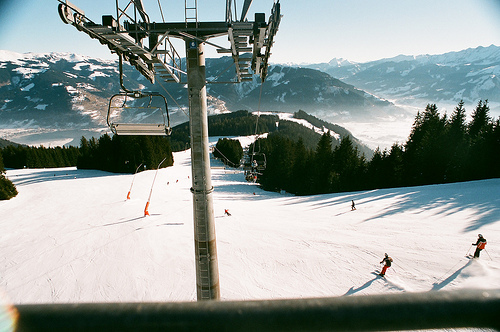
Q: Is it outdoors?
A: Yes, it is outdoors.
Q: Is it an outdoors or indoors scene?
A: It is outdoors.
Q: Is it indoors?
A: No, it is outdoors.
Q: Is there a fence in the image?
A: No, there are no fences.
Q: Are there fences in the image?
A: No, there are no fences.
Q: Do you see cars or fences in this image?
A: No, there are no fences or cars.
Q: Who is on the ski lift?
A: The people are on the ski lift.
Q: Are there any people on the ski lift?
A: Yes, there are people on the ski lift.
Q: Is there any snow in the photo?
A: Yes, there is snow.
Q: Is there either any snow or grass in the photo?
A: Yes, there is snow.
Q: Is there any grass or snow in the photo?
A: Yes, there is snow.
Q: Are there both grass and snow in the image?
A: No, there is snow but no grass.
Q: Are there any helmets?
A: No, there are no helmets.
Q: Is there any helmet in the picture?
A: No, there are no helmets.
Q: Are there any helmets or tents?
A: No, there are no helmets or tents.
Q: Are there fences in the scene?
A: No, there are no fences.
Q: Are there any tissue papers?
A: No, there are no tissue papers.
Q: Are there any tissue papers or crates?
A: No, there are no tissue papers or crates.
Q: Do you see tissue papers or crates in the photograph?
A: No, there are no tissue papers or crates.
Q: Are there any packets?
A: No, there are no packets.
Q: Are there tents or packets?
A: No, there are no packets or tents.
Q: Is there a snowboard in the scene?
A: No, there are no snowboards.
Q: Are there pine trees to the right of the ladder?
A: Yes, there are pine trees to the right of the ladder.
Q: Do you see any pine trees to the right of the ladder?
A: Yes, there are pine trees to the right of the ladder.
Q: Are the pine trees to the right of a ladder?
A: Yes, the pine trees are to the right of a ladder.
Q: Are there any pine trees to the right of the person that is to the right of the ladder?
A: Yes, there are pine trees to the right of the person.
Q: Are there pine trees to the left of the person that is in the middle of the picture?
A: No, the pine trees are to the right of the person.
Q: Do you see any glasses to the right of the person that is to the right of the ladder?
A: No, there are pine trees to the right of the person.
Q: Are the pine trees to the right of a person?
A: Yes, the pine trees are to the right of a person.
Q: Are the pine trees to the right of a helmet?
A: No, the pine trees are to the right of a person.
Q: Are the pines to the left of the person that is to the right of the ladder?
A: No, the pines are to the right of the person.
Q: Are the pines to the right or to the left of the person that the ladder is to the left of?
A: The pines are to the right of the person.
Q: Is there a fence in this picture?
A: No, there are no fences.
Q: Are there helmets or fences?
A: No, there are no fences or helmets.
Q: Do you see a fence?
A: No, there are no fences.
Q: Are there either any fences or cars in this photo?
A: No, there are no fences or cars.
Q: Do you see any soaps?
A: No, there are no soaps.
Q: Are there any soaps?
A: No, there are no soaps.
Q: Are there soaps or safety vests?
A: No, there are no soaps or safety vests.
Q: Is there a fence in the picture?
A: No, there are no fences.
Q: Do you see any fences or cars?
A: No, there are no fences or cars.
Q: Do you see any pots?
A: No, there are no pots.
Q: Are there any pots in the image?
A: No, there are no pots.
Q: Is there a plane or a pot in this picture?
A: No, there are no pots or airplanes.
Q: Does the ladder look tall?
A: Yes, the ladder is tall.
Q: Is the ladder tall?
A: Yes, the ladder is tall.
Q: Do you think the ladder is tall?
A: Yes, the ladder is tall.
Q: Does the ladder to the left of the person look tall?
A: Yes, the ladder is tall.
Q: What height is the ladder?
A: The ladder is tall.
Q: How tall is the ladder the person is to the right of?
A: The ladder is tall.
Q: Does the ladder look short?
A: No, the ladder is tall.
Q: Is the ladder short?
A: No, the ladder is tall.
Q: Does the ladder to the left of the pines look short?
A: No, the ladder is tall.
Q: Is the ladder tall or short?
A: The ladder is tall.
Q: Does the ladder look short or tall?
A: The ladder is tall.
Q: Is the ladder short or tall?
A: The ladder is tall.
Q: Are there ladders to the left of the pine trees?
A: Yes, there is a ladder to the left of the pine trees.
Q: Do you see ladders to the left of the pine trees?
A: Yes, there is a ladder to the left of the pine trees.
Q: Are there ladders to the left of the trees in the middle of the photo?
A: Yes, there is a ladder to the left of the pine trees.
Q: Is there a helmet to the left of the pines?
A: No, there is a ladder to the left of the pines.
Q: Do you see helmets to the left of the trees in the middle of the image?
A: No, there is a ladder to the left of the pines.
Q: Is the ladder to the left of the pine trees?
A: Yes, the ladder is to the left of the pine trees.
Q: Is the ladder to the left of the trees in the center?
A: Yes, the ladder is to the left of the pine trees.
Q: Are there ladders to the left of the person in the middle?
A: Yes, there is a ladder to the left of the person.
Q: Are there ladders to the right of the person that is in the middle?
A: No, the ladder is to the left of the person.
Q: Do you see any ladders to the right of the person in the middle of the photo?
A: No, the ladder is to the left of the person.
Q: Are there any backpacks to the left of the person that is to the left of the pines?
A: No, there is a ladder to the left of the person.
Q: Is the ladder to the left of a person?
A: Yes, the ladder is to the left of a person.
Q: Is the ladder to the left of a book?
A: No, the ladder is to the left of a person.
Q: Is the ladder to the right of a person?
A: No, the ladder is to the left of a person.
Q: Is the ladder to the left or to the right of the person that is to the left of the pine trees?
A: The ladder is to the left of the person.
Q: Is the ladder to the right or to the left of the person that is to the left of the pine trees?
A: The ladder is to the left of the person.